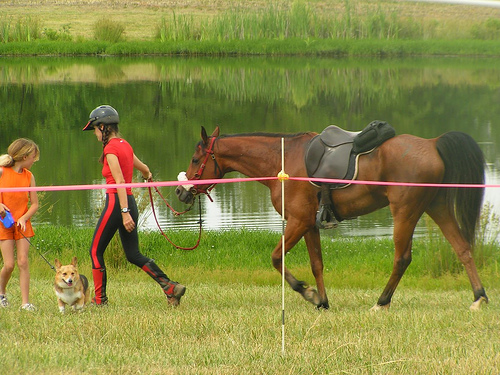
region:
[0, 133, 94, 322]
The dog is on a leash.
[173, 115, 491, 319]
The horse is brown and black.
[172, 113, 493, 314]
The horse is walking.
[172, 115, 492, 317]
The horse is wearing a saddle.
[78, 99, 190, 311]
The girl is walking.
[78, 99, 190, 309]
The girl is wearing a helmet.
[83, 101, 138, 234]
The girl is wearing a watch.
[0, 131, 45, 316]
The girl is wearing shorts.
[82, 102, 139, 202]
The girl is wearing a shirt.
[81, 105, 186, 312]
The girl is wearing pants.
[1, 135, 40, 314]
girl wearing all orange outfit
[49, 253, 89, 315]
adult brown and black corgi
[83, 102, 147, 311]
girl wearing red and black outfit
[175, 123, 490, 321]
brown horse with saddle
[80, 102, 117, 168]
head with braided pigtails and helmet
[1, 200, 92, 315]
corgi on a leach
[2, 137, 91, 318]
young girl with corgi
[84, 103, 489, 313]
girl leading a horse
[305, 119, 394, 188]
black horse saddle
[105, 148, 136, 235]
girl arm with watch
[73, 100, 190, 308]
Woman wearing black helmet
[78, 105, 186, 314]
Woman wearing red top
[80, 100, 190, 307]
Woman wearing black pants with red stripe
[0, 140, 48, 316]
Young girl wearing orange jumper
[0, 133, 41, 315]
Young girl walking dog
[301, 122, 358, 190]
Saddle on horse is black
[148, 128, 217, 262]
Harness on horse is red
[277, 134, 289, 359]
White stick stuck in grass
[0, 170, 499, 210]
Pink rope attached to white stick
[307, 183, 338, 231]
Brown stirrup attached to saddle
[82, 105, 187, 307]
Woman walking on the grass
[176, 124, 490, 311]
Horse walking on the grass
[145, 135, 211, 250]
Rope on the horse's face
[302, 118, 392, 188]
Saddle on the horse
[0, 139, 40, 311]
Girl standing on the grass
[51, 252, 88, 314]
Dog standing on the grass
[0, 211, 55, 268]
Leash on the dog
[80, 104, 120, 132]
Helmet on the woman's head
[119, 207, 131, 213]
Watch on the woman's wrist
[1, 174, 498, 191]
Pink rope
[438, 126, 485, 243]
Black thick tale of horse.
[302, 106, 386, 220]
Dark colored horse saddle.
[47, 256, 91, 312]
Little dog playing in field.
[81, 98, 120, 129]
Black and red helmet worn by a person.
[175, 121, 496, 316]
Brown horse with dark saddle.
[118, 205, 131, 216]
Dark watch being worn by a woman.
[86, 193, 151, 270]
Black pants with red stripe.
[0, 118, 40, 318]
Little girl in orange outfit.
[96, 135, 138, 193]
Red shirt being worn by a woman.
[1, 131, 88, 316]
Little blonde girl walking a dog.